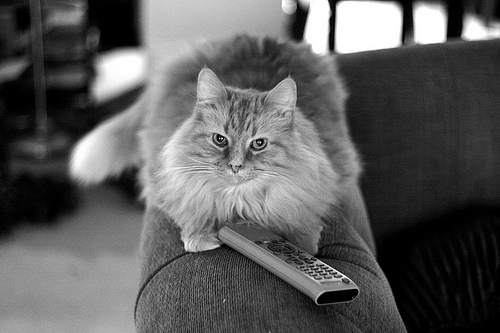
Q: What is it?
A: Cat.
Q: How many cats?
A: 1.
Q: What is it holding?
A: Remote.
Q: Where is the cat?
A: Couch.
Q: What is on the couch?
A: Cat.